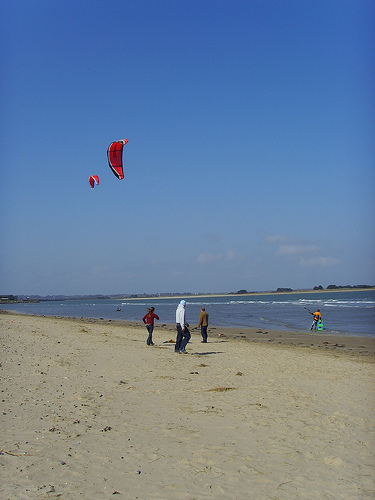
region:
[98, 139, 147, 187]
kite in the sky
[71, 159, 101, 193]
kite in the sky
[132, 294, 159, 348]
boy wearing a red shirt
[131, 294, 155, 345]
boy wearing blue jeans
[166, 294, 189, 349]
man wearing gray shirt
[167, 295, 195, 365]
man wearing blue jeans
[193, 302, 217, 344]
man wearing brown jacket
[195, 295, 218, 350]
man wearing blue jeans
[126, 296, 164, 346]
boy on a beach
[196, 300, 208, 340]
man on a beach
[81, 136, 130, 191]
Two kites in the air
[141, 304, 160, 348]
Girl wearing red shirt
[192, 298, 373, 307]
Waves in the water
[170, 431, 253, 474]
Sandy beach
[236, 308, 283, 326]
Blue water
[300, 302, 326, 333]
Person flying a kite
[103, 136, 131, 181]
A red, white and blue kite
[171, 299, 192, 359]
Person is wearing a white hoodie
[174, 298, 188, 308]
Person is wearing a blue hoodie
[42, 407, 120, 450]
Rocks on the beach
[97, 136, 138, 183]
a kite in the air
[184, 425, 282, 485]
the sand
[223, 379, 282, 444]
the sand is brown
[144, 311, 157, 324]
a red shirt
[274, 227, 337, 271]
clouds in the sky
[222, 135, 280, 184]
the sky is clear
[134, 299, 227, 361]
three people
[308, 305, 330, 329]
a person in the water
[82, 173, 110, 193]
a kite in the sky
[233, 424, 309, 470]
the sand is brown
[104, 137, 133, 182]
Red kite flying in sky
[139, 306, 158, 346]
Woman walking on beach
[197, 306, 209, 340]
Man in brown shirt on beach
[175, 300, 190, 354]
Man in white shirt on beach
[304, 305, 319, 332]
Man in orange shirt wading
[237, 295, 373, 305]
White line of water on wave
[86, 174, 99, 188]
Red kite with white trim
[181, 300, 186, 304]
Blue hat on man's head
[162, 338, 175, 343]
Kite lying on the ground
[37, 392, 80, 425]
Rocks buried in sand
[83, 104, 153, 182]
a red and black kite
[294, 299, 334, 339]
a man kiteboarding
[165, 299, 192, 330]
a man in a hooded sweatshirt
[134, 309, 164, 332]
a woman in a red sweater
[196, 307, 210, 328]
a man in a brown sweater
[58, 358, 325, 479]
a vast sandy beach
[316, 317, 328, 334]
a neon green kiteboard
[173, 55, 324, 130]
a cloudless blue sky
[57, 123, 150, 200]
a set of red kites flying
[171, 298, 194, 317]
a man in a light blue knit hat